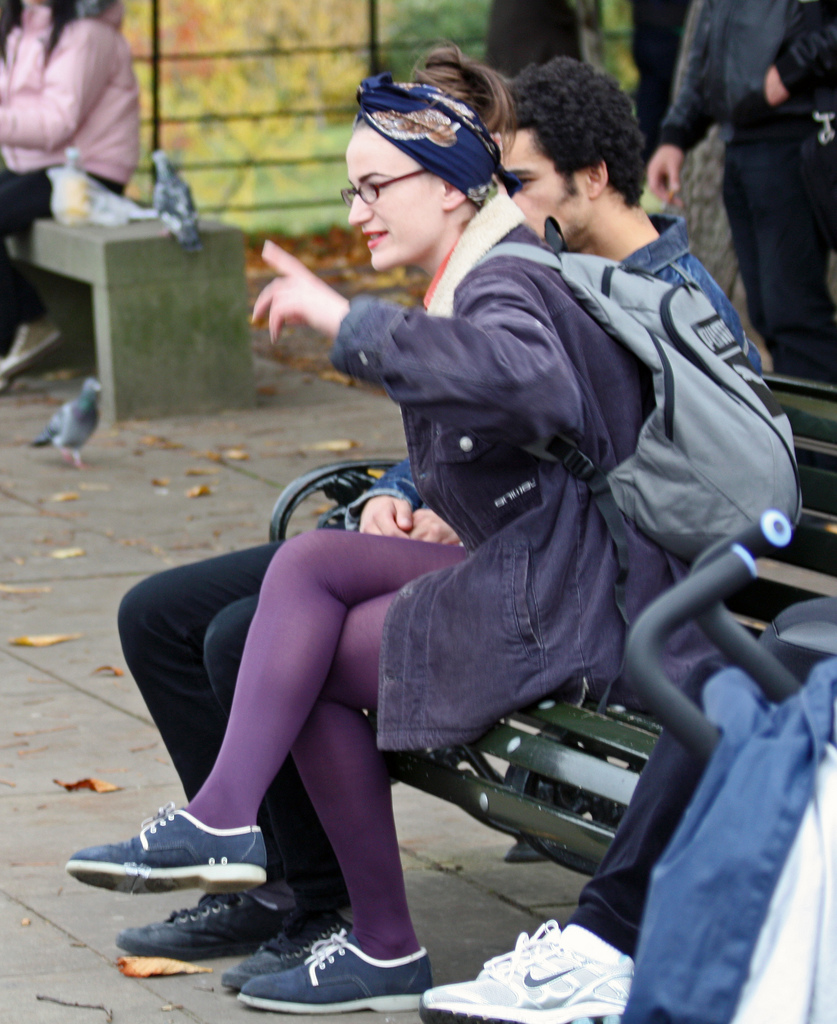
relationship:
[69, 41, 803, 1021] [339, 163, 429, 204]
woman wearing glasses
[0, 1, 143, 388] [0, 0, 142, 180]
lady wearing coat